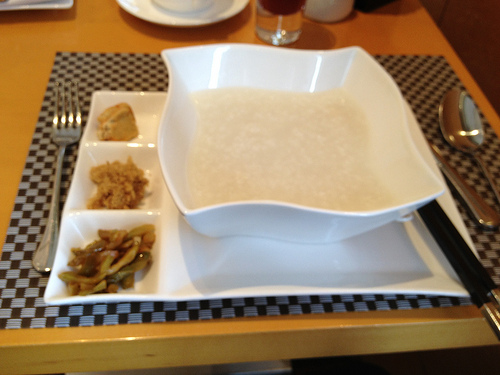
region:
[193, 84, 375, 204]
a bowl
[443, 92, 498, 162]
a silver spoon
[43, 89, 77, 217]
a fork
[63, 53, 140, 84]
a table mat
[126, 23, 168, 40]
a shadow on the table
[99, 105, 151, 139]
food on the plate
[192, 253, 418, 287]
a shadow on the plate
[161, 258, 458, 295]
the plate is white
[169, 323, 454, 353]
the table is brown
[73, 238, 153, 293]
food on the plate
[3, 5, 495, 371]
Place setting with a meal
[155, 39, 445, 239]
A geometric bowl full of soup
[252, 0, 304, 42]
Clear glass of water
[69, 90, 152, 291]
Food items in a individual sections on white plate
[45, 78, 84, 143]
four tines of a fork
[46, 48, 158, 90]
grey and black checker patterned placemat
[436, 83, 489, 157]
silver spoon reflecting light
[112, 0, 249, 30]
section of saucer and mug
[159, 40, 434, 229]
white liquid inside of a white bowl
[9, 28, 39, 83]
laquered wood dining table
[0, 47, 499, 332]
black and gray checkered placemat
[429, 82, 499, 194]
silver spoon on a placemat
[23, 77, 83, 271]
silver fork on a placemat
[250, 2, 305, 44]
drinking glass on a table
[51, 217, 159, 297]
green beans on a white plate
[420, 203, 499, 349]
knife on the edge of a white plate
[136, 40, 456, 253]
white bowl on a plate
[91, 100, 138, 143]
brown paste on a white plate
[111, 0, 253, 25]
white saucer on a table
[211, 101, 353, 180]
creamy white liquid in a bowl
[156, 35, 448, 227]
Bowl of white rice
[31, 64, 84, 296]
Silver fork eating utinsel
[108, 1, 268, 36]
tea cup saucer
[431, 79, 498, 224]
Silver spoon eating utensil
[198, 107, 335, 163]
White rice that has been cooked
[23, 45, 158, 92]
Checkerboard patter for place mat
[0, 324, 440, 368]
Wooden side of table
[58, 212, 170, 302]
Cooked green pepper and onion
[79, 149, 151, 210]
Zested ginger rood side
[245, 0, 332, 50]
small glass of soki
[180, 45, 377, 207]
A bowl of white soup.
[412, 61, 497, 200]
A spoon on the table.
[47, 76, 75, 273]
A fork on the left of the plate.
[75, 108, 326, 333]
The plate is white.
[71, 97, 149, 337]
Food on the side of the plate.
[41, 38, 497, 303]
A plate on top of the table mat.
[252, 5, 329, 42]
A glass of water on the table.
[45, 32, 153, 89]
The table mat is black and white checkered.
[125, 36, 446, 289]
The bowl is on top of the plate.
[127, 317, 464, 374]
The table is wooden.